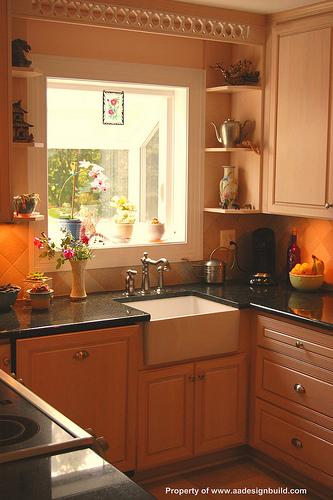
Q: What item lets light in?
A: A window.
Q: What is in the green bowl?
A: Fruit.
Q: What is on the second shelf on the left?
A: House.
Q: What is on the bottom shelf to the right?
A: Vase.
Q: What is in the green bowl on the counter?
A: Fruit.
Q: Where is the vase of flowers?
A: Next to the sink.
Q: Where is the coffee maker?
A: In the corner.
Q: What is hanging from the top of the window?
A: A glass image.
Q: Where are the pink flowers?
A: In the vase.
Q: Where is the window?
A: Above the sink.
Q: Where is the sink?
A: Under the window.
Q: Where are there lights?
A: Under the cabinets?.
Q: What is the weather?
A: Sunny.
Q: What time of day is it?
A: Morning.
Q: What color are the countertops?
A: Black.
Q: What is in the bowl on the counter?
A: Fruit.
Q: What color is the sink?
A: White.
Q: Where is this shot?
A: Kitchen.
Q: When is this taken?
A: Daytime.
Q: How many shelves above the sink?
A: 6.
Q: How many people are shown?
A: 0.